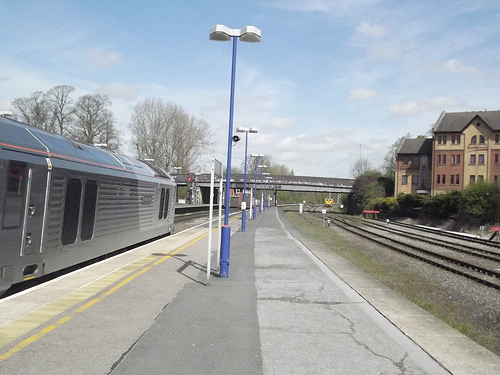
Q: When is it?
A: Day time.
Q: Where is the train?
A: On the tracks.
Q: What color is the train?
A: Silver.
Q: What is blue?
A: The sky.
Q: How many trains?
A: 1.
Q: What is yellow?
A: Stripes.